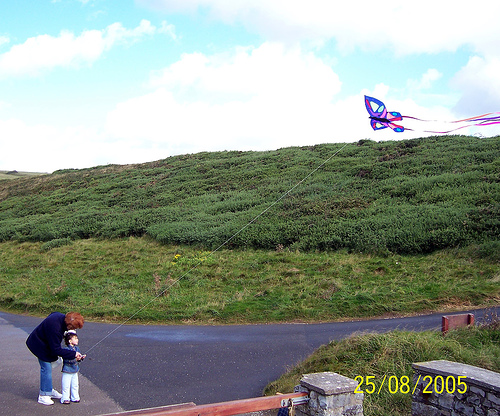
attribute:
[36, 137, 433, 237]
green field — large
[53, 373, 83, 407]
pants — white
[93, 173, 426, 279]
grass — green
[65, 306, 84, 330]
hair — red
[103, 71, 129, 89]
sky — blue